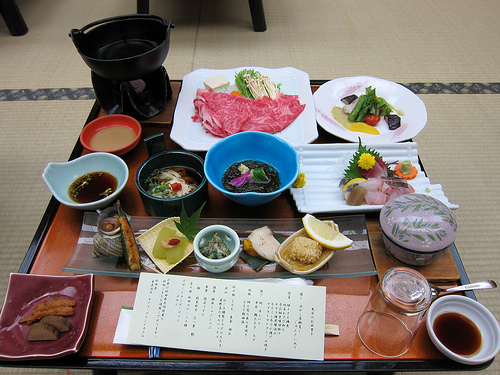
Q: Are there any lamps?
A: No, there are no lamps.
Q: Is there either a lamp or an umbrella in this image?
A: No, there are no lamps or umbrellas.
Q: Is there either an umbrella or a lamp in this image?
A: No, there are no lamps or umbrellas.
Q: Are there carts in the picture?
A: No, there are no carts.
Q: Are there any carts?
A: No, there are no carts.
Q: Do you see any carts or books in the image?
A: No, there are no carts or books.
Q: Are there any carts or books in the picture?
A: No, there are no carts or books.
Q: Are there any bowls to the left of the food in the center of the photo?
A: Yes, there is a bowl to the left of the food.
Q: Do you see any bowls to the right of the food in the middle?
A: No, the bowl is to the left of the food.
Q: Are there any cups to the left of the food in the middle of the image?
A: No, there is a bowl to the left of the food.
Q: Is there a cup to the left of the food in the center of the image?
A: No, there is a bowl to the left of the food.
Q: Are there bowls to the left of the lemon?
A: Yes, there is a bowl to the left of the lemon.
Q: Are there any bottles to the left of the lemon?
A: No, there is a bowl to the left of the lemon.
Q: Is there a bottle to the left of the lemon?
A: No, there is a bowl to the left of the lemon.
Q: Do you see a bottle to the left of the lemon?
A: No, there is a bowl to the left of the lemon.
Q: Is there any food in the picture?
A: Yes, there is food.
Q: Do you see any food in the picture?
A: Yes, there is food.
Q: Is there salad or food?
A: Yes, there is food.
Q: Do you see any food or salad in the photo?
A: Yes, there is food.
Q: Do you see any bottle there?
A: No, there are no bottles.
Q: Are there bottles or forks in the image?
A: No, there are no bottles or forks.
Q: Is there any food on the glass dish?
A: Yes, there is food on the dish.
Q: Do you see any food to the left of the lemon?
A: Yes, there is food to the left of the lemon.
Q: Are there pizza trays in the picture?
A: No, there are no pizza trays.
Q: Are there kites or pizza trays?
A: No, there are no pizza trays or kites.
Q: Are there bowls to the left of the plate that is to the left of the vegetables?
A: Yes, there is a bowl to the left of the plate.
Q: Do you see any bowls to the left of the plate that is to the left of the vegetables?
A: Yes, there is a bowl to the left of the plate.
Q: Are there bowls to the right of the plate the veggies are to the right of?
A: No, the bowl is to the left of the plate.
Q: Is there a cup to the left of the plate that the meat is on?
A: No, there is a bowl to the left of the plate.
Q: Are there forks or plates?
A: Yes, there is a plate.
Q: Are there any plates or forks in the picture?
A: Yes, there is a plate.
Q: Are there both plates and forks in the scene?
A: No, there is a plate but no forks.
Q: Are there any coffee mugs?
A: No, there are no coffee mugs.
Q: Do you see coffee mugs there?
A: No, there are no coffee mugs.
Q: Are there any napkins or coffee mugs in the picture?
A: No, there are no coffee mugs or napkins.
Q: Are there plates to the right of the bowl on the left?
A: Yes, there is a plate to the right of the bowl.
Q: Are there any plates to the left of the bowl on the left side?
A: No, the plate is to the right of the bowl.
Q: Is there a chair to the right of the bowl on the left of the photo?
A: No, there is a plate to the right of the bowl.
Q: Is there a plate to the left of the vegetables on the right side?
A: Yes, there is a plate to the left of the vegetables.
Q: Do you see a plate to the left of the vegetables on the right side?
A: Yes, there is a plate to the left of the vegetables.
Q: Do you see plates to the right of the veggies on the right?
A: No, the plate is to the left of the vegetables.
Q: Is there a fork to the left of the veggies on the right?
A: No, there is a plate to the left of the veggies.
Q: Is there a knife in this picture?
A: No, there are no knives.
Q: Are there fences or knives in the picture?
A: No, there are no knives or fences.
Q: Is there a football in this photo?
A: No, there are no footballs.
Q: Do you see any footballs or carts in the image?
A: No, there are no footballs or carts.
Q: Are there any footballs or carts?
A: No, there are no footballs or carts.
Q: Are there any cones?
A: No, there are no cones.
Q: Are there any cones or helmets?
A: No, there are no cones or helmets.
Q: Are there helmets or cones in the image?
A: No, there are no cones or helmets.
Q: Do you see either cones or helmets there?
A: No, there are no cones or helmets.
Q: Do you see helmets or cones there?
A: No, there are no cones or helmets.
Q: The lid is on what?
A: The lid is on the dish.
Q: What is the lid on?
A: The lid is on the dish.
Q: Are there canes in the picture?
A: No, there are no canes.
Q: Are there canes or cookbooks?
A: No, there are no canes or cookbooks.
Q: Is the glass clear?
A: Yes, the glass is clear.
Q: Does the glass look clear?
A: Yes, the glass is clear.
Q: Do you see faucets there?
A: No, there are no faucets.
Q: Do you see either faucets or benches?
A: No, there are no faucets or benches.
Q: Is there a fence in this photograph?
A: No, there are no fences.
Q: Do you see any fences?
A: No, there are no fences.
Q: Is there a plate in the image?
A: Yes, there is a plate.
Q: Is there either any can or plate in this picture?
A: Yes, there is a plate.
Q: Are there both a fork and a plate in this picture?
A: No, there is a plate but no forks.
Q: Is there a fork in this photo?
A: No, there are no forks.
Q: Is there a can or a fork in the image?
A: No, there are no forks or cans.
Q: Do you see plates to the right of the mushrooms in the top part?
A: Yes, there is a plate to the right of the mushrooms.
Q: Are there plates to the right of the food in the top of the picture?
A: Yes, there is a plate to the right of the mushrooms.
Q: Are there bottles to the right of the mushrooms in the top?
A: No, there is a plate to the right of the mushrooms.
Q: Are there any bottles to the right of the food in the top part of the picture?
A: No, there is a plate to the right of the mushrooms.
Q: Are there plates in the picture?
A: Yes, there is a plate.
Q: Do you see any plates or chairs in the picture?
A: Yes, there is a plate.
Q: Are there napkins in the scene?
A: No, there are no napkins.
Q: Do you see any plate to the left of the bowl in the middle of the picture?
A: No, the plate is to the right of the bowl.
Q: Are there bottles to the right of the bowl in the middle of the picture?
A: No, there is a plate to the right of the bowl.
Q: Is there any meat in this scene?
A: Yes, there is meat.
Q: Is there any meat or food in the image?
A: Yes, there is meat.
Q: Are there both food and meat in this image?
A: Yes, there are both meat and food.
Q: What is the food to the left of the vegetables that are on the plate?
A: The food is meat.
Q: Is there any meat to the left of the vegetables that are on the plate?
A: Yes, there is meat to the left of the veggies.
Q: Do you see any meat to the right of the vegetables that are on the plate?
A: No, the meat is to the left of the vegetables.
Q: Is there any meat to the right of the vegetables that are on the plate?
A: No, the meat is to the left of the vegetables.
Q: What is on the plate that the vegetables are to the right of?
A: The meat is on the plate.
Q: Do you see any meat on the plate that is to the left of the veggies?
A: Yes, there is meat on the plate.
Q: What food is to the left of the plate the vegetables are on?
A: The food is meat.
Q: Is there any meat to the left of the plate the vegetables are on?
A: Yes, there is meat to the left of the plate.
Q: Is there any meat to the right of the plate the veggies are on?
A: No, the meat is to the left of the plate.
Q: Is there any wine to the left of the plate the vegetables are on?
A: No, there is meat to the left of the plate.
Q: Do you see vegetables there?
A: Yes, there are vegetables.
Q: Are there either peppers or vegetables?
A: Yes, there are vegetables.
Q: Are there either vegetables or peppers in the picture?
A: Yes, there are vegetables.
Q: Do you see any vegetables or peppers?
A: Yes, there are vegetables.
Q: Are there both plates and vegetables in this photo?
A: Yes, there are both vegetables and a plate.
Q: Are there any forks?
A: No, there are no forks.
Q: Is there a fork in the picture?
A: No, there are no forks.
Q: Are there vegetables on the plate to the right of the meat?
A: Yes, there are vegetables on the plate.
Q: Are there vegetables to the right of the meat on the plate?
A: Yes, there are vegetables to the right of the meat.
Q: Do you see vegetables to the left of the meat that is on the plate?
A: No, the vegetables are to the right of the meat.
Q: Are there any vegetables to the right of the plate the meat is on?
A: Yes, there are vegetables to the right of the plate.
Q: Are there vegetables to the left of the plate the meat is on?
A: No, the vegetables are to the right of the plate.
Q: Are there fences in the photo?
A: No, there are no fences.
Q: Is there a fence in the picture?
A: No, there are no fences.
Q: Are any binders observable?
A: No, there are no binders.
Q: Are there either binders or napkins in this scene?
A: No, there are no binders or napkins.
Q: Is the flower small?
A: Yes, the flower is small.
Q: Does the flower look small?
A: Yes, the flower is small.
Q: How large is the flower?
A: The flower is small.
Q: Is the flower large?
A: No, the flower is small.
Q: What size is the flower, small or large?
A: The flower is small.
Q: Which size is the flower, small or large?
A: The flower is small.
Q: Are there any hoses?
A: No, there are no hoses.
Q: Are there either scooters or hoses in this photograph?
A: No, there are no hoses or scooters.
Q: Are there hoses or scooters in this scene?
A: No, there are no hoses or scooters.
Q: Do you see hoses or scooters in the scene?
A: No, there are no hoses or scooters.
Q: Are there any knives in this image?
A: No, there are no knives.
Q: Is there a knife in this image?
A: No, there are no knives.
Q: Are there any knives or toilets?
A: No, there are no knives or toilets.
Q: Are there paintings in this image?
A: No, there are no paintings.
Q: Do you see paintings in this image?
A: No, there are no paintings.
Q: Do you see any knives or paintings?
A: No, there are no paintings or knives.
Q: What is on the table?
A: The menu is on the table.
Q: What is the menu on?
A: The menu is on the table.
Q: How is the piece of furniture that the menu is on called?
A: The piece of furniture is a table.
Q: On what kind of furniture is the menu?
A: The menu is on the table.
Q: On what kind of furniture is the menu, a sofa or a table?
A: The menu is on a table.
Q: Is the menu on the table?
A: Yes, the menu is on the table.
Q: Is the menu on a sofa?
A: No, the menu is on the table.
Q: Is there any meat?
A: Yes, there is meat.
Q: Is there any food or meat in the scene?
A: Yes, there is meat.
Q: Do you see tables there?
A: Yes, there is a table.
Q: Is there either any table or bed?
A: Yes, there is a table.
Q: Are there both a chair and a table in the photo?
A: No, there is a table but no chairs.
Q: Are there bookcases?
A: No, there are no bookcases.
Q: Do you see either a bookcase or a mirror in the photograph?
A: No, there are no bookcases or mirrors.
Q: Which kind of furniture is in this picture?
A: The furniture is a table.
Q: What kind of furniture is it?
A: The piece of furniture is a table.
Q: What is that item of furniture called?
A: This is a table.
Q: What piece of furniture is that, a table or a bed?
A: This is a table.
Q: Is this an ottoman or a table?
A: This is a table.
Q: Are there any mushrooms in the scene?
A: Yes, there are mushrooms.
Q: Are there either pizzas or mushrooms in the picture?
A: Yes, there are mushrooms.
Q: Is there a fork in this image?
A: No, there are no forks.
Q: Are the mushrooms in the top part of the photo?
A: Yes, the mushrooms are in the top of the image.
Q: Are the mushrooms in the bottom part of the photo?
A: No, the mushrooms are in the top of the image.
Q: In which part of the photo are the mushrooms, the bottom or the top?
A: The mushrooms are in the top of the image.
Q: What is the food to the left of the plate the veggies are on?
A: The food is mushrooms.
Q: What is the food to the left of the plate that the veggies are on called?
A: The food is mushrooms.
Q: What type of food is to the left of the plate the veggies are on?
A: The food is mushrooms.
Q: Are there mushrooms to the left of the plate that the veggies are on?
A: Yes, there are mushrooms to the left of the plate.